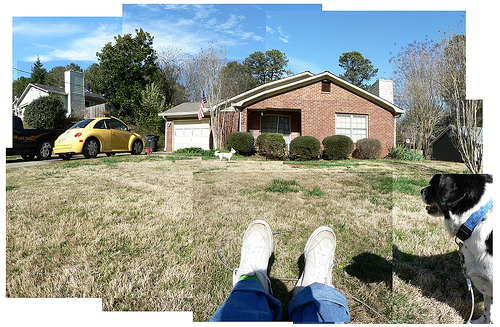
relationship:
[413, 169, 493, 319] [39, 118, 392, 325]
dog in yard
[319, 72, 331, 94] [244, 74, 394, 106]
vents in attic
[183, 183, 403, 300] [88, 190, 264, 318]
shoes on grass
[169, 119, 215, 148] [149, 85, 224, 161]
door on garage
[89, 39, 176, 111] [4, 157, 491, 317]
tree in field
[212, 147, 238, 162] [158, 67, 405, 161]
white dog in front of house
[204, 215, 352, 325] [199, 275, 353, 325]
person wearing blue pants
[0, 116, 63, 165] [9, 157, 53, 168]
truck parked on driveway